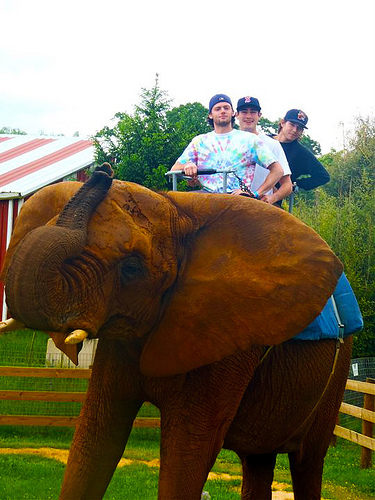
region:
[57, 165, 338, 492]
orange and brown elephant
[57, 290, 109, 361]
elephant has white tusks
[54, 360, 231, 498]
elephant has brown legs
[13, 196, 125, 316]
elephant has brown trunk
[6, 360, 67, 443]
brown fence behind elephant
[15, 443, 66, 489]
green grass behind elephant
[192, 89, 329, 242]
three boys on elephant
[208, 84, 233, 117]
boy has blue cap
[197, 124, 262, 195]
boy has tie-dye shirt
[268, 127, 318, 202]
boy has green shirt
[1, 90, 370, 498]
three guys riding an elephant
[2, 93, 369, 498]
an elephant carrying three guys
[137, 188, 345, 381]
a floppy ear of an elephant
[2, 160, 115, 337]
a trunk of an elephant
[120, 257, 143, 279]
an eye of an elephant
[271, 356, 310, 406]
a wrinkled body part of an elephant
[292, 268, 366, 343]
a blue pad on the elephant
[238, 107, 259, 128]
a facial expression of a guy on the elephant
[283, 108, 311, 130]
a baseball on the guy's head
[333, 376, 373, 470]
a wooden fence in the background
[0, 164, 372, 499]
big elephant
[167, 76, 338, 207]
three guys with hats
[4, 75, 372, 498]
three guys on a elephant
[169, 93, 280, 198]
guy wearing a tye dye shirt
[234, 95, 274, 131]
guy smiling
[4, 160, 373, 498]
big muddy elephant on the grass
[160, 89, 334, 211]
three guys sitting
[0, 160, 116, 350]
big dirty elephant truck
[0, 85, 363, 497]
big brown elephant with three guys sitting on it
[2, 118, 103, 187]
red and white tent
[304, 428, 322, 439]
part of an elephant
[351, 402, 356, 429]
part of a fence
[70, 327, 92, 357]
part of a horn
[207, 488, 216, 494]
part of a rock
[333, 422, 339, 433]
side of a fence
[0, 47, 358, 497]
Three guys riding elephant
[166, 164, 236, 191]
Hand grasping steel handle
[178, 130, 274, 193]
Tie dyed t-shirt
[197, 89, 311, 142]
Three guys with baseball caps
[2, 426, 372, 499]
Elephant standing on grass and dirt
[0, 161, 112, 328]
Trunk curled on elephant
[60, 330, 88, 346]
Ivory elephant tusk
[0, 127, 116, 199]
Red and white building roof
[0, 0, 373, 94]
White overcast skies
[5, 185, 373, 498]
Elephant in wooden enclosure